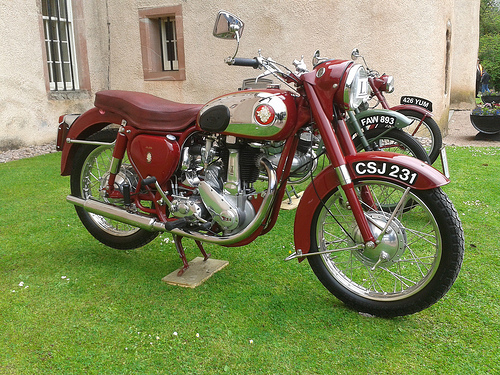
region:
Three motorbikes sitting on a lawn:
[49, 10, 469, 324]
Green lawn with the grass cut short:
[3, 143, 497, 373]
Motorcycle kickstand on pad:
[158, 234, 230, 289]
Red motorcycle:
[53, 11, 460, 317]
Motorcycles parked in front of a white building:
[3, 3, 470, 323]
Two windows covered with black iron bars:
[36, 0, 186, 100]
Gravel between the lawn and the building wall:
[1, 139, 58, 165]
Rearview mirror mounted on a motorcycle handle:
[212, 8, 271, 68]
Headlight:
[338, 59, 371, 111]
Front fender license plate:
[389, 93, 434, 114]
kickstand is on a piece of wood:
[177, 252, 256, 290]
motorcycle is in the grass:
[310, 265, 423, 346]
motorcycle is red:
[108, 98, 163, 146]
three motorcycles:
[361, 72, 417, 203]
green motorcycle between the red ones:
[351, 104, 388, 128]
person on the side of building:
[471, 56, 489, 91]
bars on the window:
[21, 50, 98, 91]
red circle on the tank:
[254, 101, 288, 134]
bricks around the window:
[147, 56, 205, 94]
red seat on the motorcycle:
[115, 69, 162, 109]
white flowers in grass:
[123, 310, 223, 373]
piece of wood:
[159, 240, 231, 312]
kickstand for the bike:
[149, 225, 216, 286]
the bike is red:
[48, 78, 420, 238]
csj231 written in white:
[335, 150, 436, 198]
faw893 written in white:
[362, 102, 398, 136]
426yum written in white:
[393, 80, 434, 114]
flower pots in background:
[463, 67, 495, 126]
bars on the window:
[28, 6, 115, 104]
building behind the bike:
[11, 71, 113, 158]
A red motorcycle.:
[55, 9, 466, 317]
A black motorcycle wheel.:
[305, 175, 467, 315]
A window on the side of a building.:
[142, 10, 181, 72]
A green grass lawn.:
[0, 145, 497, 374]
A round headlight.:
[342, 62, 367, 106]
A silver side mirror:
[212, 9, 244, 39]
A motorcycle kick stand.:
[174, 231, 211, 276]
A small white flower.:
[172, 331, 179, 336]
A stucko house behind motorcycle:
[0, 0, 480, 142]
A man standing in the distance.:
[479, 69, 490, 98]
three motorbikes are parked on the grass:
[54, 11, 466, 321]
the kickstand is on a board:
[160, 229, 217, 285]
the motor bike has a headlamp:
[337, 57, 374, 114]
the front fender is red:
[284, 148, 451, 268]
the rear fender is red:
[56, 110, 133, 177]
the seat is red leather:
[93, 83, 200, 136]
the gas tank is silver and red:
[197, 89, 297, 144]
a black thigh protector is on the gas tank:
[194, 101, 231, 139]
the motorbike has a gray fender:
[346, 105, 413, 140]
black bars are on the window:
[38, 0, 85, 98]